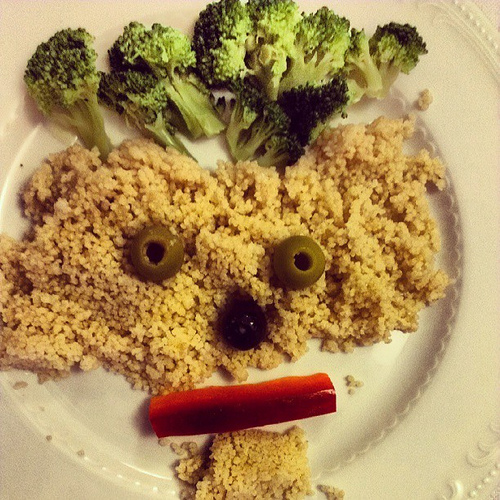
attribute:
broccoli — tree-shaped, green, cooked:
[54, 34, 389, 133]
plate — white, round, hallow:
[9, 56, 480, 498]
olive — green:
[125, 203, 191, 268]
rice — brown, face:
[50, 126, 397, 351]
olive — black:
[224, 294, 276, 339]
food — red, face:
[144, 173, 481, 370]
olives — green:
[119, 209, 364, 282]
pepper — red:
[137, 362, 341, 434]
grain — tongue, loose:
[185, 402, 341, 493]